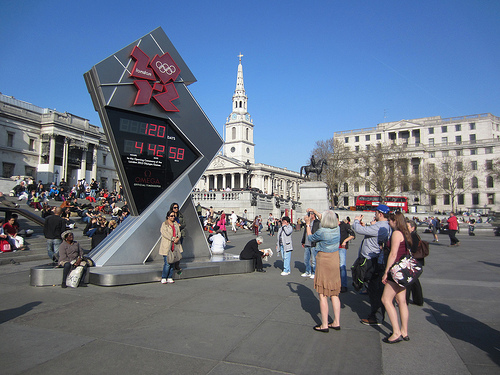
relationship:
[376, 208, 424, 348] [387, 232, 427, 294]
woman holding bag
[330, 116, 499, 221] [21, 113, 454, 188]
building in back ground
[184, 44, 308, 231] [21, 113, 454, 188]
building in back ground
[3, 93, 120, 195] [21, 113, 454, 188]
building in back ground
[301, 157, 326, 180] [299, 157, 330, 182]
statue of horse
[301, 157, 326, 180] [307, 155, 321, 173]
statue of rider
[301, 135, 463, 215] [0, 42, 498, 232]
trees near buildings